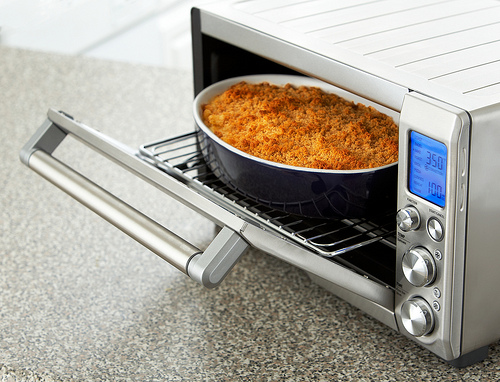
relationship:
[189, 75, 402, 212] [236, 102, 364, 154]
dish filled with food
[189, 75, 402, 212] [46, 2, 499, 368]
dish inside oven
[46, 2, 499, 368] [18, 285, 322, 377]
oven on top of granite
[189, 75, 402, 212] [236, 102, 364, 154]
dish filled with casserole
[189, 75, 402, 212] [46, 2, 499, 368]
dish inside of oven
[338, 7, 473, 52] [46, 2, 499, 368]
indentations on top of oven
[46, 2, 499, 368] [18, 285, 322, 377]
oven sitting on top of counter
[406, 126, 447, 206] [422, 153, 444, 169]
panel says 350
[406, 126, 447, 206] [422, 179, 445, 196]
panel says 100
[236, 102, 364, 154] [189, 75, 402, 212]
food inside of bowl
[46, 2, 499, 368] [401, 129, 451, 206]
oven has information panel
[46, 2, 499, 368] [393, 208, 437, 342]
oven has silver dials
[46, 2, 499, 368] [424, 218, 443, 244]
oven has silver button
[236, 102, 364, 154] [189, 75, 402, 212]
food ide of bowl